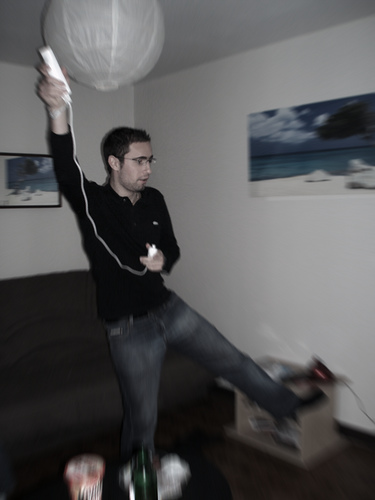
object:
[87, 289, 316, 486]
jeans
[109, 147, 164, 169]
small glasses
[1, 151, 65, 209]
picture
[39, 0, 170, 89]
round lamp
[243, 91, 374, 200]
picture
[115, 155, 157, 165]
eyeglasses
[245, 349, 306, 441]
table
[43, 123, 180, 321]
shirt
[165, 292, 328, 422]
leg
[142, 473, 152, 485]
green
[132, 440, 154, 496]
bottle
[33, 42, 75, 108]
remote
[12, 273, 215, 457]
gray sofa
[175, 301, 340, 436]
left leg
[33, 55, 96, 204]
right arm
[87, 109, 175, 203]
head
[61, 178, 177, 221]
shoulders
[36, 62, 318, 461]
guy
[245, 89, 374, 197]
poster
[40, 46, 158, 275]
remote controller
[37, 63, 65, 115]
hand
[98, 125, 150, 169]
hair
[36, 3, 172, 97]
lantern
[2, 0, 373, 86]
ceiling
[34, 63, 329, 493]
man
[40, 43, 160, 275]
game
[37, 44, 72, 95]
wiimote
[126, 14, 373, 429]
wall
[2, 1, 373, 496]
room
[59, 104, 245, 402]
torso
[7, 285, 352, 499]
floor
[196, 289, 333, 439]
air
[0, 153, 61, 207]
frame